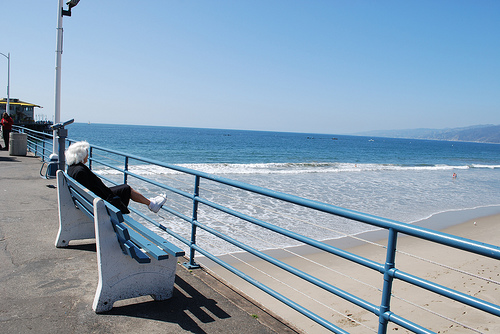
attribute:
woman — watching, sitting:
[63, 138, 167, 216]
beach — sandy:
[128, 173, 499, 281]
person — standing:
[1, 109, 13, 150]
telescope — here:
[50, 117, 71, 175]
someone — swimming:
[451, 169, 457, 180]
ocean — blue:
[95, 126, 494, 189]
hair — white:
[64, 140, 90, 166]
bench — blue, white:
[55, 169, 186, 309]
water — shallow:
[394, 190, 498, 222]